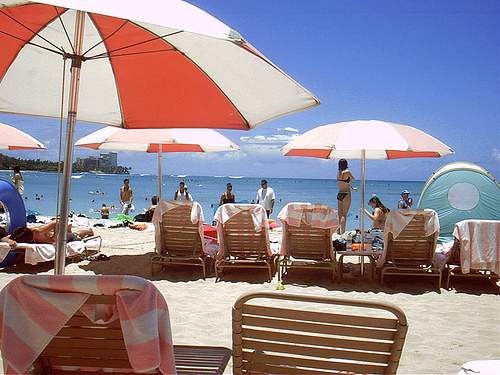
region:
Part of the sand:
[428, 307, 473, 347]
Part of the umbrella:
[338, 132, 365, 141]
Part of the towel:
[23, 298, 40, 318]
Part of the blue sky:
[455, 105, 467, 133]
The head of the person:
[258, 177, 270, 189]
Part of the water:
[295, 189, 312, 197]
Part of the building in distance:
[105, 157, 112, 163]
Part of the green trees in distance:
[28, 161, 38, 168]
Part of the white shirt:
[265, 196, 267, 203]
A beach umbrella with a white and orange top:
[1, 0, 321, 276]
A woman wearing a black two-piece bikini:
[336, 158, 357, 235]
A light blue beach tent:
[415, 160, 499, 246]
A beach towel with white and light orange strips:
[1, 274, 177, 374]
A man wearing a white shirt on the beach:
[256, 179, 275, 221]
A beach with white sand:
[2, 219, 499, 374]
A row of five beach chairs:
[154, 203, 499, 295]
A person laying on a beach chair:
[0, 218, 102, 265]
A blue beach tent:
[0, 179, 29, 234]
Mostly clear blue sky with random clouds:
[0, 0, 499, 184]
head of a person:
[173, 173, 187, 195]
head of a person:
[223, 175, 237, 193]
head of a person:
[254, 173, 271, 193]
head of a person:
[335, 153, 351, 175]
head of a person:
[402, 182, 414, 203]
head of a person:
[94, 197, 110, 207]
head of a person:
[12, 160, 26, 173]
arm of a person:
[263, 182, 280, 214]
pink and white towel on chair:
[211, 196, 276, 280]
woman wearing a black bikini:
[327, 155, 373, 244]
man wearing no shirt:
[110, 171, 135, 226]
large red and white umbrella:
[296, 113, 441, 165]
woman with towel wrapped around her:
[7, 160, 34, 204]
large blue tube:
[3, 177, 26, 233]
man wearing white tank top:
[172, 178, 192, 203]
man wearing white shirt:
[251, 177, 271, 210]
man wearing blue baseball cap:
[399, 181, 414, 209]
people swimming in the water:
[27, 182, 106, 209]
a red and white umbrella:
[283, 110, 498, 191]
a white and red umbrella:
[63, 121, 253, 193]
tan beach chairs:
[139, 178, 494, 288]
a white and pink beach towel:
[1, 261, 180, 371]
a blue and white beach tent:
[383, 138, 498, 235]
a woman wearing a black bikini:
[308, 146, 363, 236]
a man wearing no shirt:
[106, 175, 151, 229]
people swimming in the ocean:
[13, 158, 170, 234]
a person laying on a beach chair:
[3, 211, 115, 273]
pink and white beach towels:
[139, 183, 338, 265]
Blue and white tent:
[413, 154, 499, 242]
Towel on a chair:
[3, 270, 180, 372]